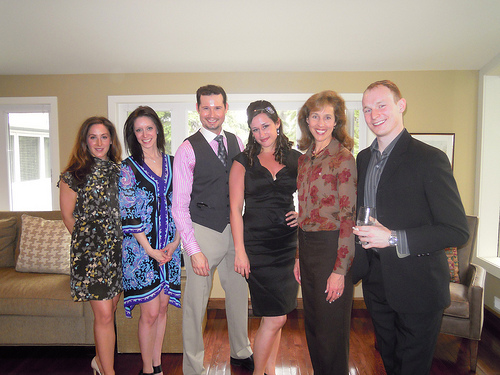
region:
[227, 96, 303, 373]
woman wearing a black dress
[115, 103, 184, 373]
beautiful woman in black and blue dress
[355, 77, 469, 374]
man holding a glass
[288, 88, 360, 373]
woman wearing floral shirt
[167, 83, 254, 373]
man in suit vest and striped shirt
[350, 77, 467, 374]
man wearing a black suit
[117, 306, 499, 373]
dark brown hardwood floor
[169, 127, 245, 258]
vest worn over pink striped shirt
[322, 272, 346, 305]
painted finger nails on hand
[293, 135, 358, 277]
blouse made with autumn leaves fabric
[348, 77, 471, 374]
man holding a wine glass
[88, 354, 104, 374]
white high heel shoe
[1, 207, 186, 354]
tan couch with beige patterned pillow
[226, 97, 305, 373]
woman holding her hand on her hip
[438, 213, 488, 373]
chair with decorative pillow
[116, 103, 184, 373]
woman standing with hands folded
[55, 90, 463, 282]
a group of people standing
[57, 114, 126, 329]
woman in a colorful dress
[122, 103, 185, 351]
woman in a purple dress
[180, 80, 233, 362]
man wearing a tie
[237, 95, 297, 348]
woman in a black dress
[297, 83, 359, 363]
womanin black pants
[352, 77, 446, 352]
a man wearing a suit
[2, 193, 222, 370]
a brown couch in the back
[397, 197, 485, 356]
a chair behing a man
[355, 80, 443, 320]
a man holding a glass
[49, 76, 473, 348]
A group of people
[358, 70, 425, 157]
The man is smiling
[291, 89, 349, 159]
The woman is smiling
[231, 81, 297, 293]
The woman has a dress on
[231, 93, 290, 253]
The woman has a black dress on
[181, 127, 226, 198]
The man has a vest on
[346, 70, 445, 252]
The man has a drink in his hand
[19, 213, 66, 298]
Pillow on a couch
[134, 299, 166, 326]
Knees of a woman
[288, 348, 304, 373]
Hard wood floor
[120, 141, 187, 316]
woman in blue paisley dress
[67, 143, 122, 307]
black multicolored dot dress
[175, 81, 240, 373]
man in pink long sleeve and vest